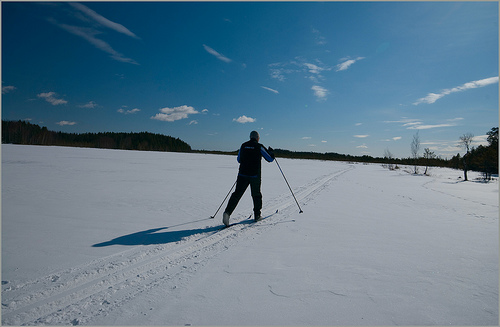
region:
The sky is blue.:
[388, 5, 493, 54]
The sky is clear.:
[147, 2, 189, 80]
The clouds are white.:
[191, 34, 296, 108]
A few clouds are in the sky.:
[172, 35, 296, 103]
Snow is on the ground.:
[329, 221, 454, 316]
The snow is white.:
[328, 236, 480, 315]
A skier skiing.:
[159, 115, 329, 247]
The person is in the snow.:
[186, 121, 323, 249]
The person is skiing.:
[181, 117, 334, 254]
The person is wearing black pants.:
[206, 165, 302, 239]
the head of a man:
[247, 126, 263, 144]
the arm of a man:
[258, 142, 277, 164]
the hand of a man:
[265, 142, 278, 157]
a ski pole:
[273, 155, 307, 215]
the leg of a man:
[248, 177, 264, 214]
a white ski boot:
[220, 208, 232, 228]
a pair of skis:
[186, 205, 281, 249]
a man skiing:
[205, 122, 313, 237]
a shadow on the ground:
[88, 217, 239, 257]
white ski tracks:
[0, 159, 362, 325]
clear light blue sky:
[252, 25, 442, 117]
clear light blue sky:
[153, 15, 413, 94]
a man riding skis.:
[199, 124, 311, 227]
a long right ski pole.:
[265, 146, 312, 218]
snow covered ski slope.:
[0, 139, 497, 324]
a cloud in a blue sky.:
[153, 82, 217, 134]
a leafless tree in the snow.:
[447, 126, 479, 188]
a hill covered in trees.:
[0, 117, 196, 150]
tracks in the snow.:
[0, 148, 365, 325]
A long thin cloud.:
[380, 65, 496, 111]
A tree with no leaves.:
[395, 126, 430, 176]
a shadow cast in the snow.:
[83, 197, 268, 263]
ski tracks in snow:
[145, 222, 213, 286]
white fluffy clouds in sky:
[166, 92, 208, 129]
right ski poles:
[273, 150, 309, 225]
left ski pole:
[206, 175, 252, 225]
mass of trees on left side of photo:
[21, 115, 196, 198]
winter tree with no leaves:
[400, 126, 424, 172]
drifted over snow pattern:
[372, 257, 497, 324]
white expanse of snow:
[24, 177, 117, 234]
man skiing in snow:
[219, 109, 341, 276]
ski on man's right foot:
[240, 201, 292, 243]